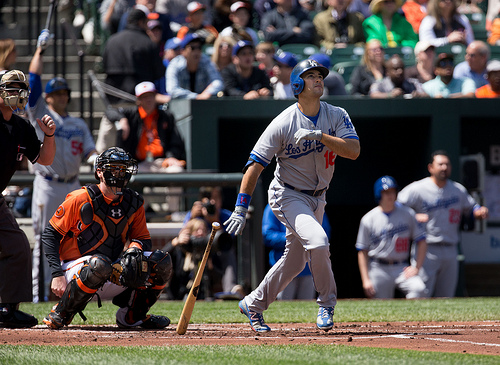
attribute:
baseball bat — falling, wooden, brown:
[175, 220, 224, 334]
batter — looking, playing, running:
[220, 56, 362, 336]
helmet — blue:
[288, 56, 329, 97]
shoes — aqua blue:
[234, 294, 345, 337]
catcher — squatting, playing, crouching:
[39, 145, 175, 333]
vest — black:
[75, 183, 146, 263]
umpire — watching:
[3, 66, 58, 333]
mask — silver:
[2, 70, 35, 115]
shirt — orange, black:
[42, 186, 154, 281]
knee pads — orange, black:
[77, 249, 173, 291]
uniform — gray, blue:
[239, 103, 355, 312]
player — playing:
[352, 175, 429, 302]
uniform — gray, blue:
[355, 206, 429, 300]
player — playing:
[397, 150, 487, 300]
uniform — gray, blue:
[394, 176, 480, 297]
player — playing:
[27, 26, 100, 306]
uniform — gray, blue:
[24, 73, 94, 304]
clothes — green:
[361, 16, 422, 52]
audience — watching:
[66, 1, 499, 98]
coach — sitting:
[116, 82, 191, 223]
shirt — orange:
[131, 104, 169, 159]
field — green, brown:
[0, 289, 498, 363]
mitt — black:
[117, 246, 154, 295]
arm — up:
[23, 28, 59, 123]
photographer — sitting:
[161, 216, 236, 297]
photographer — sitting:
[181, 183, 251, 297]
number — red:
[317, 146, 339, 179]